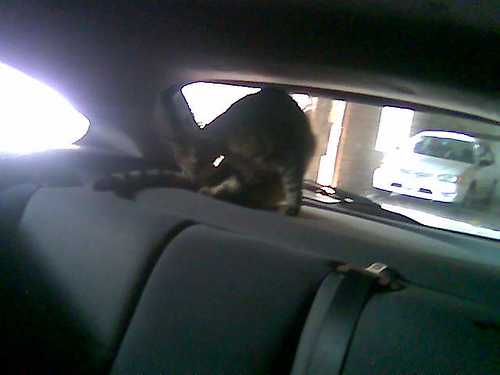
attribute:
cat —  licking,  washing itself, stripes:
[95, 92, 312, 215]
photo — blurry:
[7, 5, 490, 365]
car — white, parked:
[371, 129, 493, 206]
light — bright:
[6, 69, 306, 152]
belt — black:
[307, 261, 381, 373]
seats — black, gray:
[8, 199, 485, 371]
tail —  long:
[84, 157, 191, 195]